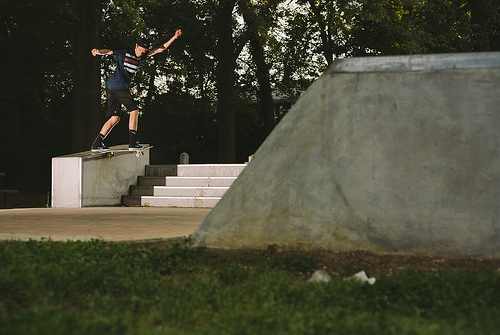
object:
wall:
[52, 158, 81, 208]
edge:
[80, 157, 84, 207]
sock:
[129, 130, 138, 143]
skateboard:
[91, 146, 153, 158]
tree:
[216, 0, 236, 164]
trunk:
[71, 0, 102, 153]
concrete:
[184, 53, 499, 260]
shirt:
[105, 50, 146, 89]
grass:
[0, 238, 499, 335]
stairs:
[137, 176, 235, 186]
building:
[243, 86, 293, 120]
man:
[91, 29, 182, 152]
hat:
[136, 39, 150, 49]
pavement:
[0, 205, 212, 243]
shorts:
[106, 87, 140, 117]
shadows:
[120, 164, 179, 207]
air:
[0, 81, 62, 140]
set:
[145, 164, 249, 177]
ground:
[0, 206, 499, 334]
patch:
[89, 260, 250, 335]